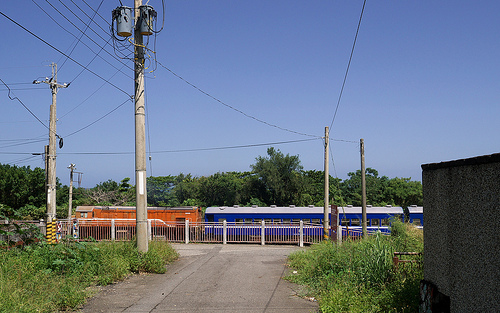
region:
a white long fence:
[163, 220, 318, 247]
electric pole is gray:
[115, 51, 159, 270]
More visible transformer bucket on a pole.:
[114, 7, 132, 38]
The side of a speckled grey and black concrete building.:
[416, 156, 499, 309]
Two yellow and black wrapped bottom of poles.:
[43, 215, 58, 245]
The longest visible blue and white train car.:
[203, 203, 403, 243]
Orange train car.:
[70, 204, 198, 236]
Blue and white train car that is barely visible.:
[407, 204, 421, 229]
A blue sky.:
[1, 2, 498, 181]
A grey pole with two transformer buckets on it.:
[133, 0, 150, 253]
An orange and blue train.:
[66, 201, 425, 241]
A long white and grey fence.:
[3, 217, 423, 247]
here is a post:
[101, 3, 206, 269]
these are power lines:
[39, 0, 404, 155]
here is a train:
[44, 152, 478, 246]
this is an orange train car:
[60, 192, 202, 240]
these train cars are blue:
[204, 189, 436, 251]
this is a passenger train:
[62, 185, 450, 273]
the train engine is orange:
[58, 182, 220, 252]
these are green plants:
[6, 223, 208, 304]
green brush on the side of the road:
[289, 233, 428, 310]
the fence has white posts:
[15, 210, 437, 265]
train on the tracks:
[76, 200, 441, 245]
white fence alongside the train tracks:
[53, 206, 423, 253]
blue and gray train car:
[197, 199, 336, 240]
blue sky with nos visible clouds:
[0, 0, 494, 191]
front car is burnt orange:
[66, 200, 206, 235]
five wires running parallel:
[36, 0, 152, 80]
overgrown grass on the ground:
[263, 215, 458, 311]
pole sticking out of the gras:
[113, 0, 168, 265]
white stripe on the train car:
[76, 213, 181, 227]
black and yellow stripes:
[45, 220, 55, 245]